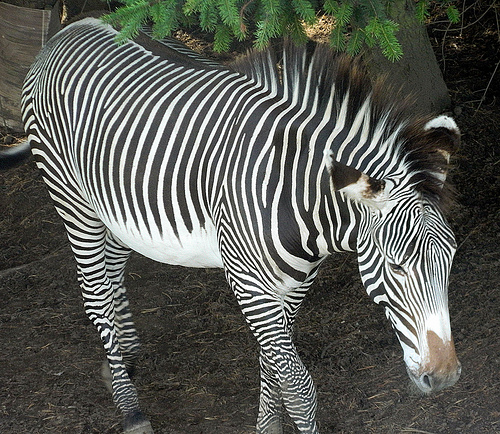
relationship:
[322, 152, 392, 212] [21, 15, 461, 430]
ear of zebra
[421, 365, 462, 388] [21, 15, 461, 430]
nose of zebra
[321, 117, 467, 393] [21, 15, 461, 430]
head of zebra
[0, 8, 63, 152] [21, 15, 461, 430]
post next to zebra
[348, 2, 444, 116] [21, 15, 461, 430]
tree trunk behind zebra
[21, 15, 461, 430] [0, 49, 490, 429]
zebra grazing in area